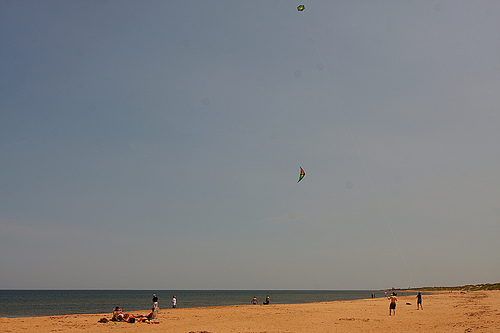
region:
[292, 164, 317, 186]
a colorful kite in midair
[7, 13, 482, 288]
a mostly clear blue sky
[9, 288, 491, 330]
a mostly level stretch of sand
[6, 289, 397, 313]
a flat, calm stretch of water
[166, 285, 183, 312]
a person in white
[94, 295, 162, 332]
people sitting on the sand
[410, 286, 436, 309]
person on a beach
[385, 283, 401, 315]
person on a beach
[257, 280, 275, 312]
person on a beach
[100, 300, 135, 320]
person on a beach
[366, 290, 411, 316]
person wearing black shorts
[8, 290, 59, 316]
water near a beach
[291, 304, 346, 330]
sand on a beach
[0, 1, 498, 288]
clear blue of daytime sky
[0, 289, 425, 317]
calm surface of water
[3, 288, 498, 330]
beach sand overlooking water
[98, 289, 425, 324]
people on surface of beach sand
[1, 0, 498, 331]
two kites flying over beach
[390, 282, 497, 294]
grass on sand bluff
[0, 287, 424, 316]
surface of blue water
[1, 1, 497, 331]
clear daytime sky above beach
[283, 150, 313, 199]
a kite in the air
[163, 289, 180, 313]
a person in white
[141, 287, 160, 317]
a person in black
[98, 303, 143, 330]
people on the ground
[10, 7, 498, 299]
a mostly clear blue sky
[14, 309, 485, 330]
a mostly level stretch of sand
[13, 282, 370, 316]
a mostly calm stretch of water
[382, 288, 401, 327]
a man flying a kite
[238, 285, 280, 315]
people walking near the water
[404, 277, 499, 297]
grassy hills in the background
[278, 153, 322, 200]
A kite in the sky.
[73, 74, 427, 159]
the sky is overcast.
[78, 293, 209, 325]
People sitting on the sand.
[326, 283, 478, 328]
People flying kites on the beach.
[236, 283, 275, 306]
People in the water.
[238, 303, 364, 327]
The sand is tan.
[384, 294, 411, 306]
The person is not wearing a shirt.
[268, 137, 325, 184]
The kite is colorful.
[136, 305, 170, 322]
A person sitting in a chair.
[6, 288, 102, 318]
The water is very calm.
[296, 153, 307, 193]
kite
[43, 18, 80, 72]
white clouds in blue sky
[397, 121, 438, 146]
white clouds in blue sky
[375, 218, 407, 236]
white clouds in blue sky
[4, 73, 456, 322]
this is a coastal area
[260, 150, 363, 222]
this is a kite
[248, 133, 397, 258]
the kite is flying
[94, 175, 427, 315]
the sky is hazy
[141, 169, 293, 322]
the sky is white and blue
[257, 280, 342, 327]
the beach is sandy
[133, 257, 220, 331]
the water is dark blue